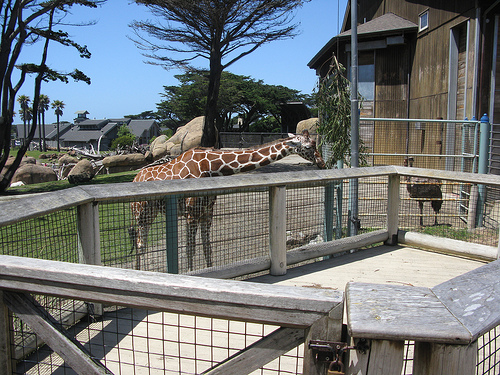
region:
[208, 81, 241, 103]
the view of a white wall and chairs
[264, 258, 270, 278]
the view of a white wall and chairs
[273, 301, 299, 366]
the view of a white wall and chairs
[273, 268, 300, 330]
the view of a white wall and chairs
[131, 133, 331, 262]
A giraffe leaning over a fence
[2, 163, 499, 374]
A small fenced enclosure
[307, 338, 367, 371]
A metal latch on a gate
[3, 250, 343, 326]
The wooden top of a gate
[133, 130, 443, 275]
the giraffe is looking at the bird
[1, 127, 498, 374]
the empty pen in front of the giraffe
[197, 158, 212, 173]
brown spot on the giraffe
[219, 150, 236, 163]
brown spot on the giraffe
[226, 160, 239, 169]
brown spot on the giraffe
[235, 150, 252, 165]
brown spot on the giraffe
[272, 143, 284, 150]
brown spot on the giraffe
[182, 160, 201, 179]
brown spot on the giraffe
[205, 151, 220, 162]
brown spot on the giraffe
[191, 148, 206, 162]
brown spot on the giraffe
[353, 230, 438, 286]
light hitting the ground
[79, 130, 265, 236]
brown and white animal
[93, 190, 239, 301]
legs of the animal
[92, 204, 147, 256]
grass on the ground